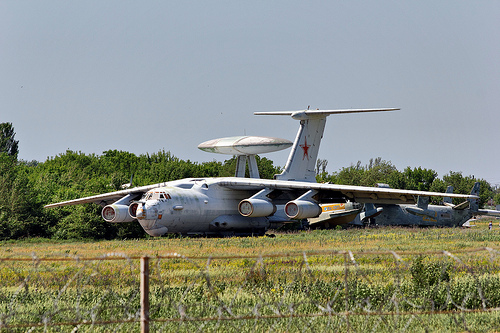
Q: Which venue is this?
A: This is a field.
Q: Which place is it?
A: It is a field.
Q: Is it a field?
A: Yes, it is a field.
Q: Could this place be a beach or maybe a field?
A: It is a field.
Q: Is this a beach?
A: No, it is a field.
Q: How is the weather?
A: It is cloudless.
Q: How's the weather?
A: It is cloudless.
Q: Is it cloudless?
A: Yes, it is cloudless.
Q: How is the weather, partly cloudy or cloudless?
A: It is cloudless.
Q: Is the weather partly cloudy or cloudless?
A: It is cloudless.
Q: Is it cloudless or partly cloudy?
A: It is cloudless.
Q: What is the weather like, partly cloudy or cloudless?
A: It is cloudless.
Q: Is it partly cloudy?
A: No, it is cloudless.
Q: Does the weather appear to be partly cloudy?
A: No, it is cloudless.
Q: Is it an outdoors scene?
A: Yes, it is outdoors.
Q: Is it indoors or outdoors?
A: It is outdoors.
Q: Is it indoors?
A: No, it is outdoors.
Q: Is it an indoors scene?
A: No, it is outdoors.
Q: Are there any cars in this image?
A: No, there are no cars.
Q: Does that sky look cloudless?
A: Yes, the sky is cloudless.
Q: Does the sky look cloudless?
A: Yes, the sky is cloudless.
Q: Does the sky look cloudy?
A: No, the sky is cloudless.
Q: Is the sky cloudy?
A: No, the sky is cloudless.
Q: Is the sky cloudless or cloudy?
A: The sky is cloudless.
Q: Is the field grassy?
A: Yes, the field is grassy.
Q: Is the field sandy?
A: No, the field is grassy.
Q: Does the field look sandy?
A: No, the field is grassy.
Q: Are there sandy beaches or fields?
A: No, there is a field but it is grassy.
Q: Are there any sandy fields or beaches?
A: No, there is a field but it is grassy.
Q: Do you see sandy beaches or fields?
A: No, there is a field but it is grassy.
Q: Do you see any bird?
A: No, there are no birds.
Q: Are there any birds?
A: No, there are no birds.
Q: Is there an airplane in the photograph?
A: Yes, there is an airplane.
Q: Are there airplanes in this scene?
A: Yes, there is an airplane.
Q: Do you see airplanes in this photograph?
A: Yes, there is an airplane.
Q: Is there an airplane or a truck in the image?
A: Yes, there is an airplane.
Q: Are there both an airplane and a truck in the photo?
A: No, there is an airplane but no trucks.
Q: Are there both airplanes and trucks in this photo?
A: No, there is an airplane but no trucks.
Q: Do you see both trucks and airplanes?
A: No, there is an airplane but no trucks.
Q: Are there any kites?
A: No, there are no kites.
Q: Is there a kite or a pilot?
A: No, there are no kites or pilots.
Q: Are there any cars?
A: No, there are no cars.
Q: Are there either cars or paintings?
A: No, there are no cars or paintings.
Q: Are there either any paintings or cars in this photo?
A: No, there are no cars or paintings.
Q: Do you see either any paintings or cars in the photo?
A: No, there are no cars or paintings.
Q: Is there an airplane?
A: Yes, there is an airplane.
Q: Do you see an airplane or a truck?
A: Yes, there is an airplane.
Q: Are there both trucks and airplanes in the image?
A: No, there is an airplane but no trucks.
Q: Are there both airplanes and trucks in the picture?
A: No, there is an airplane but no trucks.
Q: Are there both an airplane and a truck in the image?
A: No, there is an airplane but no trucks.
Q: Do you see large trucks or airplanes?
A: Yes, there is a large airplane.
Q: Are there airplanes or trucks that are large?
A: Yes, the airplane is large.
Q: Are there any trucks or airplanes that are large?
A: Yes, the airplane is large.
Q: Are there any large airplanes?
A: Yes, there is a large airplane.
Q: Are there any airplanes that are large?
A: Yes, there is an airplane that is large.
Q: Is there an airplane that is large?
A: Yes, there is an airplane that is large.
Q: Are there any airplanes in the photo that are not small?
A: Yes, there is a large airplane.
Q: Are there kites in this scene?
A: No, there are no kites.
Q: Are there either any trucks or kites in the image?
A: No, there are no kites or trucks.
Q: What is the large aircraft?
A: The aircraft is an airplane.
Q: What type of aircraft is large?
A: The aircraft is an airplane.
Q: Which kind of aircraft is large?
A: The aircraft is an airplane.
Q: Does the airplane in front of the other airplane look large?
A: Yes, the airplane is large.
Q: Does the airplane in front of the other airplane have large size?
A: Yes, the airplane is large.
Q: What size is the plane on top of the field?
A: The plane is large.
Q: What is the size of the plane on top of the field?
A: The plane is large.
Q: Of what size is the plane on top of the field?
A: The plane is large.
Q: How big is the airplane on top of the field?
A: The plane is large.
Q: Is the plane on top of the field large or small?
A: The plane is large.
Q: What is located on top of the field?
A: The airplane is on top of the field.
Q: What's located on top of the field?
A: The airplane is on top of the field.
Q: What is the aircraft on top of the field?
A: The aircraft is an airplane.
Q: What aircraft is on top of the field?
A: The aircraft is an airplane.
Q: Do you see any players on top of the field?
A: No, there is an airplane on top of the field.